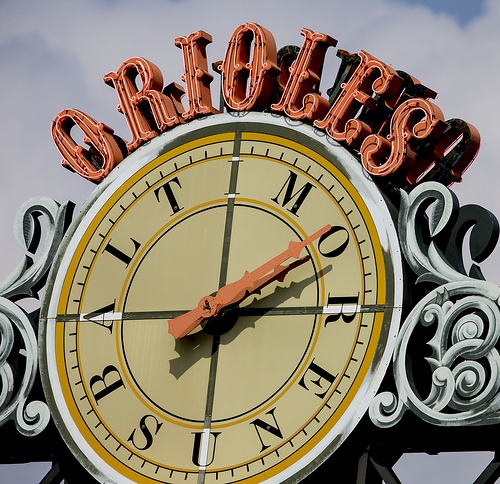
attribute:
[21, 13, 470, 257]
sign — orange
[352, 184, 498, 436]
metal — swirled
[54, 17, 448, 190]
sign — orange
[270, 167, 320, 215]
letter — M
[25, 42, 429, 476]
clock face — round, large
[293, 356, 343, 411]
e — letter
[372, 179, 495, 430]
decoration — white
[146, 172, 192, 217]
letter — black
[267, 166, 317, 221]
letter — black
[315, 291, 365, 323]
letter — black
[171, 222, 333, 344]
needle — orange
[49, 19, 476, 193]
text — red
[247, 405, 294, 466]
letter — N